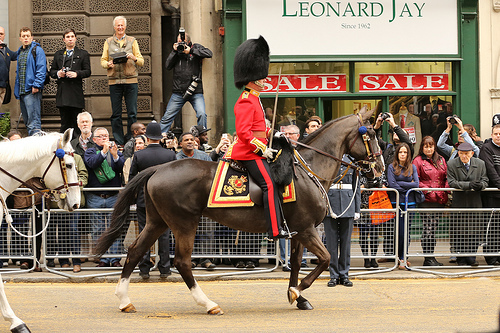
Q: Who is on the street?
A: The spectators are on the street.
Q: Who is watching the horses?
A: The people.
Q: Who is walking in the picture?
A: The man and the horse.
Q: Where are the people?
A: The people are in the city.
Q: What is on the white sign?
A: A green text.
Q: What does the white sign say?
A: The sign says Leonard Jay in green.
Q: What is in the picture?
A: A signage.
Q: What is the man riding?
A: Horse.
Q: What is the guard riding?
A: Horse.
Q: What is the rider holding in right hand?
A: Sword.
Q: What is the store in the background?
A: Leonard Jay.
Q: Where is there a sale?
A: Leonard Jay.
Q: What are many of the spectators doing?
A: Taking pictures.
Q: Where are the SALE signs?
A: Windows above the door.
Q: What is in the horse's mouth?
A: Bridle.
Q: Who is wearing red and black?
A: The man.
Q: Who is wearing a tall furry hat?
A: The man.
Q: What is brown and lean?
A: The horse.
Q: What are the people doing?
A: Watching.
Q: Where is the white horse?
A: Behind the brown horse.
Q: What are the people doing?
A: Taking pictures.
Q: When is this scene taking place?
A: Daytime.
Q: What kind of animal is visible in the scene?
A: Horse.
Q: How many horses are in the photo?
A: Two.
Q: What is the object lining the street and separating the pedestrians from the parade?
A: Fence.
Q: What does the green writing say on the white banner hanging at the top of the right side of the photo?
A: Leonard Jay since 1962.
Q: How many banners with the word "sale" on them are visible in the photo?
A: Two.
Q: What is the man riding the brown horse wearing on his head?
A: Hat.